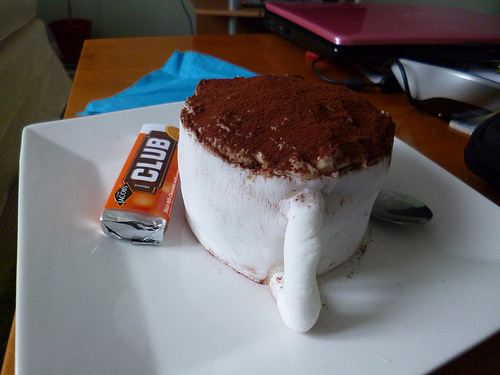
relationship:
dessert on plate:
[177, 74, 396, 333] [14, 100, 499, 374]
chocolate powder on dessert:
[182, 71, 396, 186] [179, 72, 396, 333]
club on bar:
[132, 138, 171, 182] [99, 123, 181, 245]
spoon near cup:
[371, 187, 434, 226] [178, 75, 394, 332]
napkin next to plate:
[77, 51, 260, 117] [14, 100, 499, 374]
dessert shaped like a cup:
[179, 72, 396, 333] [178, 75, 394, 332]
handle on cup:
[268, 187, 323, 333] [178, 75, 394, 332]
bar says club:
[99, 123, 181, 245] [132, 138, 171, 182]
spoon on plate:
[371, 187, 434, 226] [14, 100, 499, 374]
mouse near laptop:
[391, 55, 500, 119] [263, 0, 500, 66]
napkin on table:
[77, 51, 260, 117] [1, 33, 500, 374]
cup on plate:
[178, 75, 394, 332] [14, 100, 499, 374]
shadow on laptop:
[267, 0, 367, 39] [263, 0, 500, 66]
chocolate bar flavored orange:
[101, 122, 179, 243] [166, 123, 181, 142]